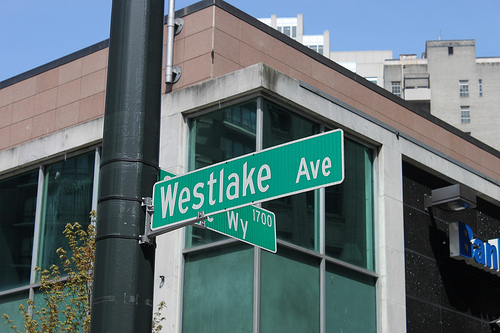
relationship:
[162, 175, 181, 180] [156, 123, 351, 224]
border around sign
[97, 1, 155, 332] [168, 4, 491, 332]
pole next to building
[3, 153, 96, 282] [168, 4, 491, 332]
window inside building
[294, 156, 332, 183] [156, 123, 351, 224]
lettering printed on sign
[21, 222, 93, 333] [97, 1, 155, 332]
tree next to pole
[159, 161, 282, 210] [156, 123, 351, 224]
lettering printed on sign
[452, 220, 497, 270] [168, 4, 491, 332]
logo hanging on building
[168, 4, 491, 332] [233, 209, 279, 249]
building behind sign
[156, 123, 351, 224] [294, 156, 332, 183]
sign has lettering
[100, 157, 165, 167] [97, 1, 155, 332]
band around pole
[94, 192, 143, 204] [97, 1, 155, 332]
band around pole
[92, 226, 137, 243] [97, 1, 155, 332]
band around pole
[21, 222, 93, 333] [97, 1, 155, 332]
tree behind pole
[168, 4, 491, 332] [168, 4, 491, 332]
building behind building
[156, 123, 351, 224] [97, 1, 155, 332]
sign attached to pole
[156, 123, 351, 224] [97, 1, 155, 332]
sign hanging on pole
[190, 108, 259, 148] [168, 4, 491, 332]
window inside building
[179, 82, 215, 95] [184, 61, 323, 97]
mark on concrete